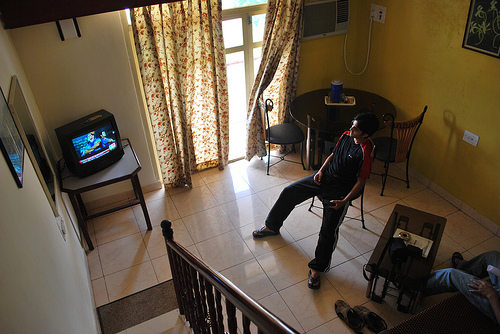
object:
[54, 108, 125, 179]
television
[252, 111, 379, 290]
man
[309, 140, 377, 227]
chair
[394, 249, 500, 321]
man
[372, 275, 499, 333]
couch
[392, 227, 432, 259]
magazine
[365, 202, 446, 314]
coffee table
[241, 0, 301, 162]
curtains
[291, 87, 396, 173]
table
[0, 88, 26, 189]
picture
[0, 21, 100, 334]
wall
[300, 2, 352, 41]
air conditioner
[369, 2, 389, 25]
electrical outlet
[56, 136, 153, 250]
table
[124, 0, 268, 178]
window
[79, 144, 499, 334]
floor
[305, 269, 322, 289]
flip flops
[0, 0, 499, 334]
room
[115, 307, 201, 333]
stairs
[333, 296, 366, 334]
shoes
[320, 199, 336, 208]
remote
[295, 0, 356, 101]
wall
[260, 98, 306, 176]
chair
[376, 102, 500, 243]
shadow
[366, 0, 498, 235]
walls